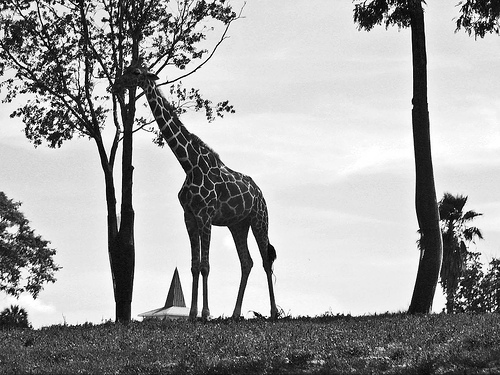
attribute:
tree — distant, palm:
[432, 186, 489, 314]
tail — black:
[251, 202, 273, 273]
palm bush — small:
[1, 304, 28, 334]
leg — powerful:
[228, 219, 249, 339]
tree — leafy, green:
[350, 0, 498, 311]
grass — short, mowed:
[290, 309, 390, 351]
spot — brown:
[192, 166, 200, 181]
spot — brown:
[202, 173, 214, 190]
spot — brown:
[214, 175, 227, 203]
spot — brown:
[224, 180, 243, 195]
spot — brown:
[230, 196, 252, 218]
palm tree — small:
[441, 190, 470, 313]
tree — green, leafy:
[4, 2, 237, 315]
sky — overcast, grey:
[1, 0, 498, 329]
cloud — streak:
[230, 52, 403, 92]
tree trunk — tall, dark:
[409, 20, 445, 313]